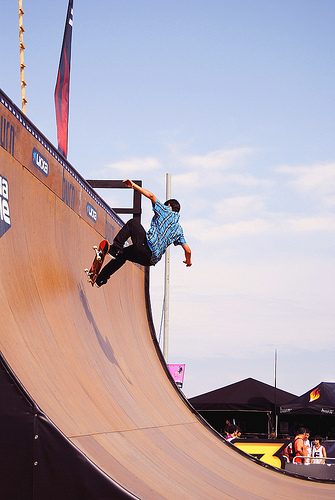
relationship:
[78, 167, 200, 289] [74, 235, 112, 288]
boy on skateboard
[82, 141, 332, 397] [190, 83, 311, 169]
clouds in sky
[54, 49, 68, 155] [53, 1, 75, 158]
flame on flag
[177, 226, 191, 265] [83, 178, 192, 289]
arm on boy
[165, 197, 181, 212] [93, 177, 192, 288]
head on person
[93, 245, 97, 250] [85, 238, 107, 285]
wheel on skateboard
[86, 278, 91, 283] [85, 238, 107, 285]
wheel on skateboard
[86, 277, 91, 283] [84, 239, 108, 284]
wheel on skateboard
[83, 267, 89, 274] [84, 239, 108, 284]
wheel on skateboard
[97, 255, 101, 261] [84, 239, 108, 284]
wheel on skateboard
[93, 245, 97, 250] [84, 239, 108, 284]
wheel on skateboard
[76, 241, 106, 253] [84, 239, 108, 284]
wheel on skateboard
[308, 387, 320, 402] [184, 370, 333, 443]
fire logo on tent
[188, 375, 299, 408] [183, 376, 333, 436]
roof on tent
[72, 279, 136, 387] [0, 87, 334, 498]
shadow on skating ramp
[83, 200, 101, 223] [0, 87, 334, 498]
logo on skating ramp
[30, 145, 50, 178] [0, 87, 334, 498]
logo on skating ramp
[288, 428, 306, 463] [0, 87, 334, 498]
person by skating ramp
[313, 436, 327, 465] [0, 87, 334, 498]
person by skating ramp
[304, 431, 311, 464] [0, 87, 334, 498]
person by skating ramp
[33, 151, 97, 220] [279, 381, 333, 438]
fire logo on tent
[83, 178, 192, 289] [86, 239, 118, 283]
boy on skateboard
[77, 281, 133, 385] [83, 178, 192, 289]
shadow from boy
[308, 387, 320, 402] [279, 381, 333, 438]
fire logo on top of tent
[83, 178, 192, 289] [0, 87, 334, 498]
boy on skating ramp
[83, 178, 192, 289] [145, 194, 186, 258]
boy wears shirt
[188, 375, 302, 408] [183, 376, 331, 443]
roof of building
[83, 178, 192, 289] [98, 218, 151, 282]
boy wears pants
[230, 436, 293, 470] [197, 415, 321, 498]
number on ground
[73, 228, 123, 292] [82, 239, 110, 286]
design on skateboard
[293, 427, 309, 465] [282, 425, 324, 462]
person are talking